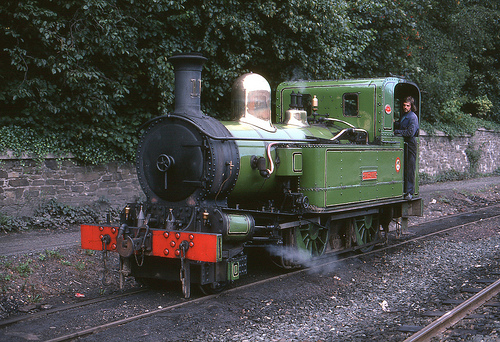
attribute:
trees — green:
[67, 15, 325, 118]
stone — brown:
[11, 179, 117, 210]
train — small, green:
[92, 59, 422, 290]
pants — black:
[404, 138, 420, 194]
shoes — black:
[406, 192, 415, 201]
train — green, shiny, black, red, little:
[78, 49, 430, 302]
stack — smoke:
[167, 47, 206, 114]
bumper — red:
[70, 220, 224, 271]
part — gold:
[234, 69, 283, 133]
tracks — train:
[26, 248, 373, 328]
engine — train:
[78, 51, 423, 297]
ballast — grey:
[269, 293, 373, 333]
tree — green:
[7, 3, 138, 123]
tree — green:
[145, 0, 262, 84]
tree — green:
[271, 2, 375, 77]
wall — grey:
[2, 120, 499, 235]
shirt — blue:
[397, 110, 420, 138]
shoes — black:
[404, 192, 415, 200]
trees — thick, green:
[3, 3, 103, 91]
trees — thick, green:
[112, 4, 238, 53]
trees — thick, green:
[203, 1, 280, 91]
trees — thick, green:
[275, 1, 378, 74]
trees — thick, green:
[373, 2, 472, 125]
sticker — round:
[151, 231, 191, 264]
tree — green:
[36, 40, 155, 160]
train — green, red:
[66, 67, 422, 302]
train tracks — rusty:
[33, 202, 495, 340]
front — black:
[136, 49, 241, 239]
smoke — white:
[256, 233, 349, 283]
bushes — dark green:
[6, 1, 496, 181]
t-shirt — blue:
[395, 107, 425, 145]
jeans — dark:
[400, 136, 420, 205]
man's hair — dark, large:
[394, 90, 419, 130]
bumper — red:
[72, 216, 225, 272]